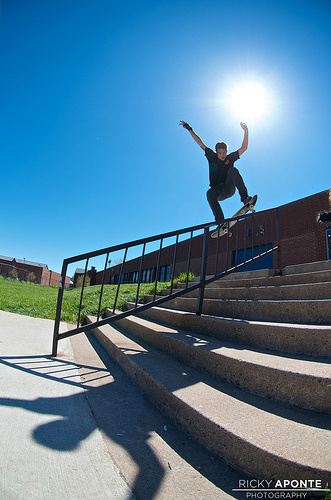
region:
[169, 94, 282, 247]
a boy on a skateboard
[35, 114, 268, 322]
a boy riding a skateboard on a hand rail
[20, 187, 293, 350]
a metal hand rail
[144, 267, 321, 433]
a set of concrete stairs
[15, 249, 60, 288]
a large red building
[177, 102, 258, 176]
a boy with his arms over his head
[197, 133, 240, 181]
a boy wearing a black shirt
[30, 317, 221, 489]
a shadow on a the ground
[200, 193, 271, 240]
a skate board with yellow wheels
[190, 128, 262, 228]
a boy wearing blue jeans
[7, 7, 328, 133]
a white sun in a blue sky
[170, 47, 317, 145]
sun is shining in a blue sky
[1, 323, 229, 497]
shadow of a person cast on ground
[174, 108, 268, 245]
skater jumping with a skateboard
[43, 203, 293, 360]
rail in middle of stairs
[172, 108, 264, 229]
skater with hands up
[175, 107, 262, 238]
skater wears black cloths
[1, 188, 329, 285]
buildings behind field cover with grass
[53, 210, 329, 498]
stairs of cement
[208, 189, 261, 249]
skateboard in the air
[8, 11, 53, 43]
this is the sky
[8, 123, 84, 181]
the sky is blue in color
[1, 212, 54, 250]
these are some clouds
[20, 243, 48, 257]
the clouds are white in color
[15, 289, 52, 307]
this is the grass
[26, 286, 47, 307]
the grass is green in color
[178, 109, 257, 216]
this is a man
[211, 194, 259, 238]
this is a skateboard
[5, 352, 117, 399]
this is the shadow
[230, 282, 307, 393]
these are the stairs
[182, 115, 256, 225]
boy is jumping on skateboard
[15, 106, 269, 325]
boy is going down black rail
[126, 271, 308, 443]
light brown steps next to railing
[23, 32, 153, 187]
sky is blue and clear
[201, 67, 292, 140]
bright sun is above boy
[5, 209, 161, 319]
green grass is on hill next to steps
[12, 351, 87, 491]
sidewalk at base of steps is grey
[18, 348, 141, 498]
boy and rail casts shadow on ground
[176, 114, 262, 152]
boy has both arms outstretched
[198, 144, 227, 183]
boy is wearing dark shirt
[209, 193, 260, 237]
a skateboard on a railing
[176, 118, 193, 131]
the boy's right hand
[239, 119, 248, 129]
the boy's left hand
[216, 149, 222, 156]
the boy's right eye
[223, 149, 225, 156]
the boy's left eye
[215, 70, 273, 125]
the bright sun in the sky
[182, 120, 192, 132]
protective gear on the boy's right hand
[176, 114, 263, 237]
a boy riding a skateboard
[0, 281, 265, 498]
the shadow of the boy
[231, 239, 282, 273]
a large blue door behind the boy